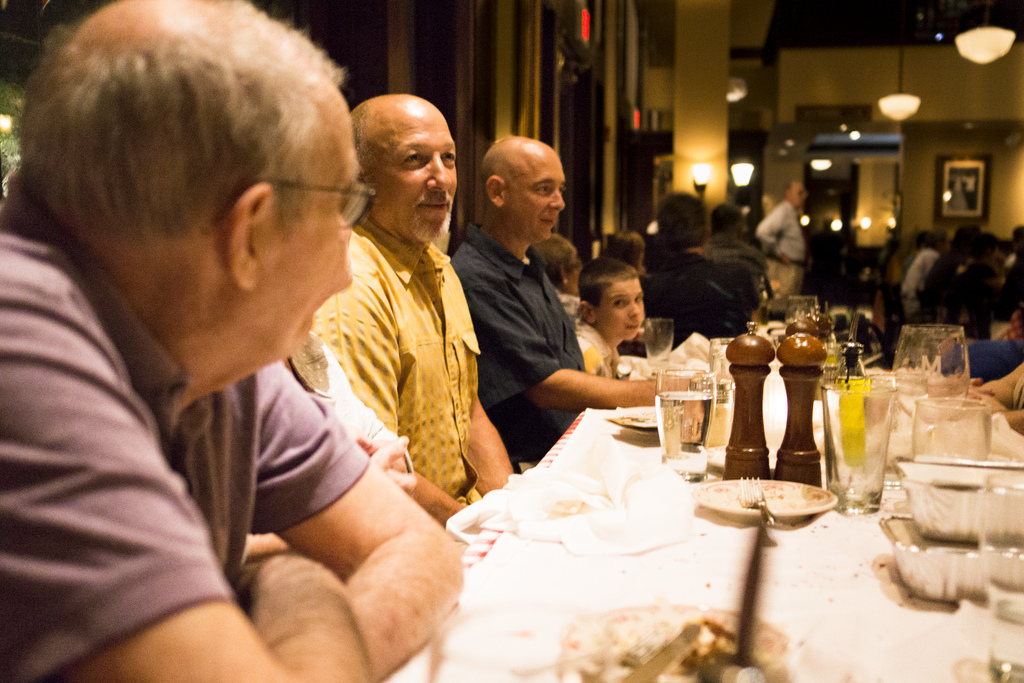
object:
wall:
[381, 2, 457, 115]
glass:
[654, 371, 719, 482]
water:
[659, 393, 713, 453]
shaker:
[722, 332, 774, 481]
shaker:
[774, 333, 828, 489]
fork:
[737, 476, 775, 525]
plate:
[695, 479, 840, 518]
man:
[447, 136, 686, 472]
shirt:
[452, 233, 584, 459]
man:
[288, 94, 507, 514]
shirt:
[299, 222, 483, 535]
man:
[0, 0, 458, 683]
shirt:
[0, 221, 369, 683]